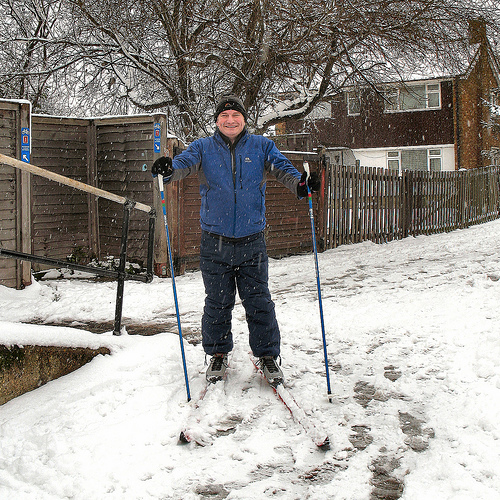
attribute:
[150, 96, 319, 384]
man — smiling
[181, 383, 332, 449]
skis — black, long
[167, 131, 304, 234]
jacket — blue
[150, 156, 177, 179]
glove — black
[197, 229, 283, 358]
snow pants — blue, dark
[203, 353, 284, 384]
shoes — gray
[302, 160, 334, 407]
pole — blue, long, white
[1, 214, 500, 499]
snow — white, scattered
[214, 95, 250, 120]
cap — gray, black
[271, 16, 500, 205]
house — brick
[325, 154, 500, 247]
fence — long, wooden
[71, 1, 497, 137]
tree — large, snow covered